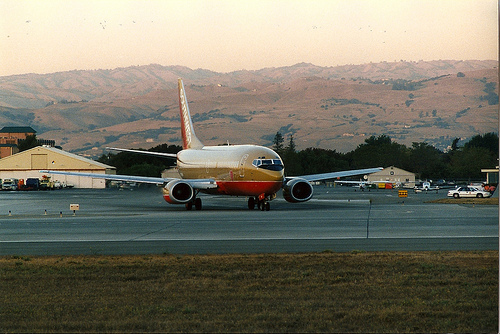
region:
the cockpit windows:
[253, 157, 283, 169]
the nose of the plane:
[256, 168, 286, 196]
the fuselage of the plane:
[183, 145, 246, 184]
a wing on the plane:
[294, 165, 388, 179]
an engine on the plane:
[161, 175, 195, 208]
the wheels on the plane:
[246, 193, 278, 217]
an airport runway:
[31, 217, 438, 261]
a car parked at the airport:
[446, 177, 488, 203]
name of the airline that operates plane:
[168, 80, 208, 150]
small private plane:
[337, 177, 397, 197]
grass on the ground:
[320, 272, 377, 331]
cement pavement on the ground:
[172, 237, 277, 251]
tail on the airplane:
[177, 75, 210, 151]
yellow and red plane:
[29, 65, 383, 217]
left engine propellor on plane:
[289, 177, 318, 204]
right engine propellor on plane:
[170, 179, 199, 206]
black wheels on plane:
[183, 195, 202, 211]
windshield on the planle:
[250, 156, 282, 170]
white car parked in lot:
[451, 183, 487, 200]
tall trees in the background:
[448, 146, 480, 188]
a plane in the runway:
[31, 74, 386, 276]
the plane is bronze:
[148, 122, 298, 205]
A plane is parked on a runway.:
[33, 72, 385, 214]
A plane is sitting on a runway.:
[39, 76, 387, 215]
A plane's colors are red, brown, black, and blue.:
[35, 75, 385, 215]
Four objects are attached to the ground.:
[2, 198, 82, 218]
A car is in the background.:
[442, 183, 493, 201]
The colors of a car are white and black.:
[444, 182, 492, 202]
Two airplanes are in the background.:
[325, 173, 460, 196]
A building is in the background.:
[357, 160, 419, 192]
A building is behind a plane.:
[0, 140, 118, 192]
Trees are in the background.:
[9, 127, 499, 187]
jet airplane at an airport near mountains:
[2, 5, 489, 329]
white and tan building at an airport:
[0, 140, 117, 192]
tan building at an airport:
[361, 163, 420, 191]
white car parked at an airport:
[443, 182, 489, 200]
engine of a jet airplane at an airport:
[280, 175, 315, 206]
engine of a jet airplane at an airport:
[162, 182, 195, 205]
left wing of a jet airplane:
[287, 165, 384, 190]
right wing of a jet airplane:
[44, 167, 216, 193]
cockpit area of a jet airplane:
[253, 154, 282, 169]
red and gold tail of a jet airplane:
[175, 78, 202, 151]